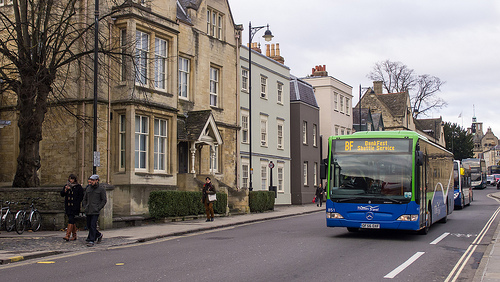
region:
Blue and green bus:
[316, 120, 484, 253]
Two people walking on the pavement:
[54, 168, 119, 248]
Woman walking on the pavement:
[193, 175, 220, 230]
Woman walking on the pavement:
[55, 168, 85, 253]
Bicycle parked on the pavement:
[12, 199, 49, 231]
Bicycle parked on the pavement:
[2, 193, 15, 227]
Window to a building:
[255, 69, 269, 105]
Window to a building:
[275, 74, 290, 111]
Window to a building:
[252, 106, 274, 158]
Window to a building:
[297, 155, 320, 192]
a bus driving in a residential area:
[113, 1, 495, 281]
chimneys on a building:
[237, 38, 289, 73]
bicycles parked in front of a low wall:
[1, 187, 62, 234]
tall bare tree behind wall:
[0, 1, 164, 228]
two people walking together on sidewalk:
[37, 172, 138, 253]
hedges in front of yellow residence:
[3, 1, 275, 223]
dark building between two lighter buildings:
[241, 39, 351, 204]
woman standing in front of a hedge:
[149, 171, 229, 228]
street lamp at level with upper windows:
[203, 11, 273, 211]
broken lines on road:
[376, 230, 460, 280]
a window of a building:
[258, 73, 272, 101]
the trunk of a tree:
[15, 105, 48, 187]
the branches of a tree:
[59, 16, 117, 61]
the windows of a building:
[133, 108, 171, 177]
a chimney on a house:
[368, 77, 388, 101]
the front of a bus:
[321, 130, 426, 231]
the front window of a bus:
[327, 151, 417, 202]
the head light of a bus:
[398, 210, 422, 225]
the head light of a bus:
[322, 208, 344, 221]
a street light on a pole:
[243, 17, 276, 71]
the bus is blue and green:
[318, 120, 453, 235]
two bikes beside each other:
[1, 194, 45, 234]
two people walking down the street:
[53, 167, 105, 249]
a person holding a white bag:
[193, 173, 222, 223]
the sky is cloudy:
[228, 2, 498, 136]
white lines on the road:
[363, 198, 495, 280]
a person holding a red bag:
[311, 178, 326, 208]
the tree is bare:
[0, 1, 175, 187]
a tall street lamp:
[246, 18, 276, 211]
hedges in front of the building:
[148, 185, 280, 217]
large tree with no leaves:
[1, 0, 193, 183]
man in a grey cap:
[82, 172, 108, 248]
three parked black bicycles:
[1, 197, 45, 235]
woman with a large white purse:
[201, 174, 219, 223]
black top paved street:
[0, 185, 499, 279]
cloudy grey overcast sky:
[227, 0, 498, 137]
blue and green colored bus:
[325, 128, 455, 236]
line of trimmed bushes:
[148, 186, 226, 219]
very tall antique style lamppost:
[243, 19, 274, 211]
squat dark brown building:
[288, 76, 325, 206]